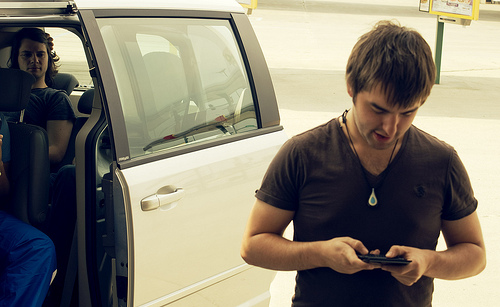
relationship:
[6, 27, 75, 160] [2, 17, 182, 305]
guy standing next to door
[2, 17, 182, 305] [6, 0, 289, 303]
door of van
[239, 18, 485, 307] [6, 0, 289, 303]
guy in back seat of van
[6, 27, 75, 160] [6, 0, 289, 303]
guy in back seat of van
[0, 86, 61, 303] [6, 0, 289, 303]
person in back seat of van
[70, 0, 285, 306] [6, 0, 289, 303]
door of van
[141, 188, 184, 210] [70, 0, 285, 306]
handle on door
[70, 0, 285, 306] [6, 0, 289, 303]
door on van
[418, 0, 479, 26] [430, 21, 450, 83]
object on pole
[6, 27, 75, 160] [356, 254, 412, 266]
guy using cell phone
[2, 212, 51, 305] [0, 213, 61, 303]
knee on a leg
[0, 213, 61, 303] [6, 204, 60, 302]
leg on a person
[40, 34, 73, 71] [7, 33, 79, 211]
hair on a person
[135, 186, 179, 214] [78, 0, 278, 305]
handle on a van door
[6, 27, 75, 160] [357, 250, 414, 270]
guy using a cell phone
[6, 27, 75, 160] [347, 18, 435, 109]
guy has hair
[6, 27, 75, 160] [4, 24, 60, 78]
guy has hair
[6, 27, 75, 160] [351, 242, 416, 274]
guy holding cell phone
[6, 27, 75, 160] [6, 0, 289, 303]
guy sitting in a van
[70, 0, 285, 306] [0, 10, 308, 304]
door on a van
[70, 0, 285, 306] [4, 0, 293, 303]
door on a car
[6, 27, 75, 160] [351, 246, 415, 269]
guy using a cell phone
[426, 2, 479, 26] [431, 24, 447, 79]
object on a post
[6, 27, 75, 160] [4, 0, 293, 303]
guy in a car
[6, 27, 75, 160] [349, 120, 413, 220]
guy wearing a necklace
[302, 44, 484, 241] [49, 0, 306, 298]
guy standing next to van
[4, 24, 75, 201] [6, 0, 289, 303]
guy inside van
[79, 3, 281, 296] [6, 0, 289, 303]
door on a van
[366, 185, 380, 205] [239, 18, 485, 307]
pendant on a guy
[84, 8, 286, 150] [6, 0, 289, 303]
window on a van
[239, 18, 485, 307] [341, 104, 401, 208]
guy wearing necklace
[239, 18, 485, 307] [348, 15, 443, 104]
guy has hair